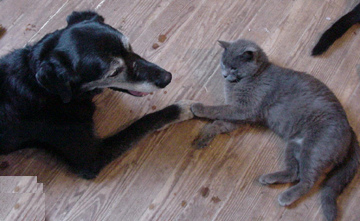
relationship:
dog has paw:
[0, 2, 199, 191] [167, 97, 200, 125]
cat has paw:
[192, 29, 357, 219] [187, 93, 219, 126]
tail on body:
[306, 138, 358, 220] [249, 62, 358, 180]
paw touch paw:
[167, 97, 200, 125] [190, 97, 207, 119]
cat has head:
[192, 29, 357, 219] [216, 34, 263, 82]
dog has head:
[0, 11, 198, 178] [56, 14, 172, 95]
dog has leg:
[0, 2, 199, 191] [48, 91, 194, 189]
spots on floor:
[180, 176, 236, 203] [134, 5, 217, 69]